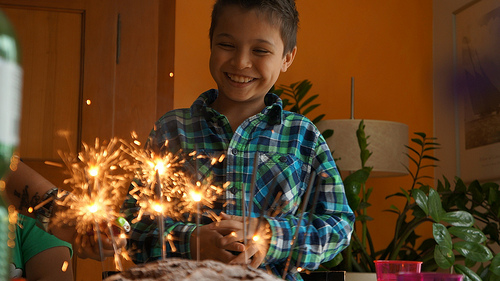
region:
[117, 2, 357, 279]
boy smiling at sparklers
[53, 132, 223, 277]
lit sparklers on cake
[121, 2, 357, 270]
boy wearing blue plaid shirt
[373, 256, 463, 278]
pink plastic drinking cups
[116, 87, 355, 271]
blue plaid shirt on young boy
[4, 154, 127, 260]
tattooed arm handling sparklers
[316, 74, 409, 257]
floor lamp behind boy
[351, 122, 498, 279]
large green house plants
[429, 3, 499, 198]
artwork hanging on wall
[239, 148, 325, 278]
unlit sparklers in cake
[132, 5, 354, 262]
smiling boy in long sleeved shirt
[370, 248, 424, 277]
rim of pink cup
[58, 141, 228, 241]
glowing lights of sparklers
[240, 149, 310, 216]
pocket on plaid shirt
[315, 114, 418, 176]
tan shade on lamp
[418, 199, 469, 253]
green leaves of plant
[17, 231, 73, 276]
short sleeve of green shirt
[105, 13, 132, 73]
hinge on wood door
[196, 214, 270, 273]
clasped hands on boy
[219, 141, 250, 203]
buttons on boy's shirt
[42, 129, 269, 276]
several sparklers stuck in a cake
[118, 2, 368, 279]
a laughing boy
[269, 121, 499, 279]
a houseplant in the background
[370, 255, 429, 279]
the top of a red plastic cup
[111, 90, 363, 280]
a plaid shirt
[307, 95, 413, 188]
a cream colored lamp shade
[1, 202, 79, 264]
the corner of a green t-shirt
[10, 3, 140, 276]
a brown cabinet door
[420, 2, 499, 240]
a painting on the wall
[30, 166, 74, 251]
a watch on a woman's wrist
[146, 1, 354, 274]
a smiling young child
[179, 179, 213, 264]
a bright candle sparkler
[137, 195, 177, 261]
a bright candle sparkler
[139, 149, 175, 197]
a bright candle sparkler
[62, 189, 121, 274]
a bright candle sparkler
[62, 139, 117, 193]
a bright candle sparkler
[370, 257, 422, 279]
a transparent red cup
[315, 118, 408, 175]
a beige lamp shade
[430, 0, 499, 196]
a framed wall print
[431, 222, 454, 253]
a green plant leaf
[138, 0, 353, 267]
boy wearing a plaid button down shirt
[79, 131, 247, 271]
sparklers on top of a cake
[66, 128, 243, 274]
sparklers lit up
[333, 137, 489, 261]
green house plants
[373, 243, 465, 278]
two pink cups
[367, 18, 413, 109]
solid painted orange walls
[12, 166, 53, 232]
person with a tatoo on their arm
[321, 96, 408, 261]
lamp with an off white lamp shade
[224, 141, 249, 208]
blue buttons on plaid shirt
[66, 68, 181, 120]
sparks of fire in the air